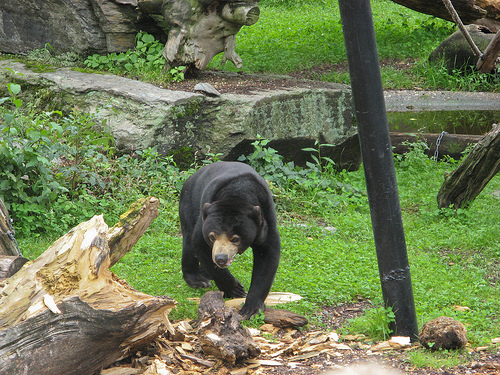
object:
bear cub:
[180, 158, 290, 315]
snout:
[210, 239, 235, 267]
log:
[6, 203, 180, 375]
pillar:
[337, 3, 418, 347]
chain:
[433, 130, 447, 164]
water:
[381, 102, 499, 138]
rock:
[24, 68, 352, 167]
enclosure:
[3, 3, 490, 374]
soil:
[163, 64, 326, 100]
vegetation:
[8, 77, 164, 238]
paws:
[180, 272, 259, 316]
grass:
[23, 177, 500, 375]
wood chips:
[174, 306, 384, 373]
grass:
[205, 0, 490, 84]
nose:
[215, 254, 228, 265]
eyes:
[206, 229, 243, 246]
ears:
[196, 199, 264, 224]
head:
[201, 201, 258, 269]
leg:
[247, 244, 279, 319]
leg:
[199, 243, 242, 297]